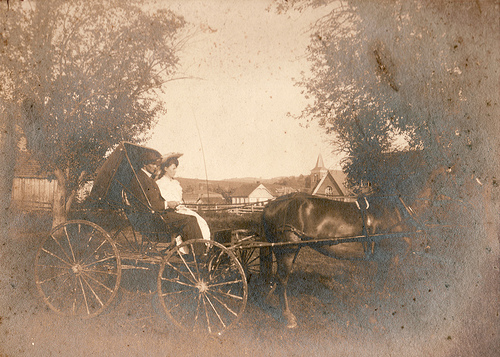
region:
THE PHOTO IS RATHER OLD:
[2, 1, 494, 351]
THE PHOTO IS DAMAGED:
[5, 10, 497, 350]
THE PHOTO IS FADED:
[5, 5, 491, 355]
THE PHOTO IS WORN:
[5, 2, 490, 343]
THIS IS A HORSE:
[255, 142, 486, 347]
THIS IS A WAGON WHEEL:
[155, 225, 261, 333]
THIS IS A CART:
[45, 183, 257, 333]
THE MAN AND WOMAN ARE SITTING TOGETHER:
[80, 132, 218, 245]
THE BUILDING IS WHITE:
[225, 175, 276, 217]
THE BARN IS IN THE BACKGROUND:
[11, 140, 119, 228]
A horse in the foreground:
[256, 158, 498, 336]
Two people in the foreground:
[130, 140, 221, 256]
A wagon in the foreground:
[15, 131, 270, 342]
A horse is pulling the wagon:
[29, 130, 491, 332]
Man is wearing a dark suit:
[128, 170, 209, 257]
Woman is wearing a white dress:
[153, 172, 218, 253]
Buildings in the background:
[188, 150, 363, 215]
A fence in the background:
[16, 163, 96, 220]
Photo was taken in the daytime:
[1, 2, 498, 354]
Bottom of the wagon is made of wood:
[28, 192, 256, 342]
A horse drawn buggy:
[36, 141, 277, 333]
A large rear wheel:
[35, 217, 120, 319]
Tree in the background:
[2, 0, 214, 236]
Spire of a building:
[310, 150, 325, 190]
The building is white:
[231, 180, 273, 210]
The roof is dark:
[229, 181, 260, 195]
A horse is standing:
[261, 157, 465, 329]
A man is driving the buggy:
[129, 154, 215, 261]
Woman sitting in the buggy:
[155, 150, 210, 250]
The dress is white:
[155, 173, 210, 248]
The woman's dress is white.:
[160, 153, 185, 196]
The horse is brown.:
[301, 201, 343, 231]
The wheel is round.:
[30, 221, 122, 321]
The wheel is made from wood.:
[30, 214, 121, 314]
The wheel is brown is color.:
[26, 219, 120, 316]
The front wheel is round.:
[157, 236, 248, 336]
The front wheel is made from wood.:
[155, 237, 247, 335]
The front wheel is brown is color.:
[158, 240, 242, 335]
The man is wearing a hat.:
[141, 151, 161, 176]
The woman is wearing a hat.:
[162, 153, 182, 175]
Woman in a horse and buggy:
[156, 153, 215, 245]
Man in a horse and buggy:
[130, 147, 164, 254]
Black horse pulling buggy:
[257, 154, 492, 335]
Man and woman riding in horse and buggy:
[50, 130, 487, 337]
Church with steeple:
[307, 146, 348, 203]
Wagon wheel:
[31, 211, 126, 326]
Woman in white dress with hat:
[163, 151, 213, 256]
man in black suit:
[134, 153, 166, 229]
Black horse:
[256, 147, 467, 336]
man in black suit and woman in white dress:
[132, 143, 216, 262]